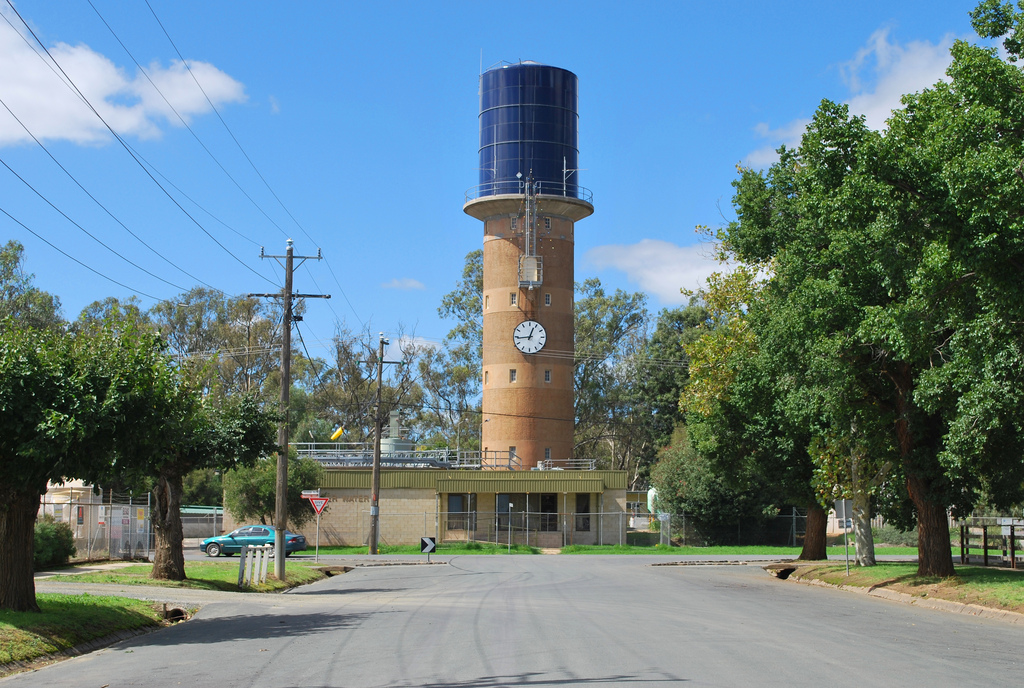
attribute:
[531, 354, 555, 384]
glass — clear, clean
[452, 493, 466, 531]
glass — clean, clear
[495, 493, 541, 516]
glass — clear, clean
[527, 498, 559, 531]
glass — clean, clear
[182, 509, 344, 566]
car — teal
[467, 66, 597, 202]
tower — dark blue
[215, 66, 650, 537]
building — brown